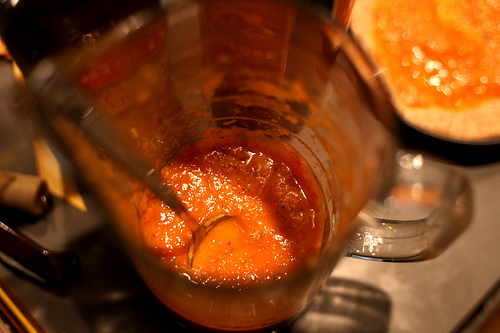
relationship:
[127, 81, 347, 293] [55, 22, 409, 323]
rings around container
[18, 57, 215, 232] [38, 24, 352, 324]
handle leaning against container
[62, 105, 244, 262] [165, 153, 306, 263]
spoon above liquid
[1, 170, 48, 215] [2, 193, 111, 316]
brown handle on top of object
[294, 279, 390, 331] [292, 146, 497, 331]
shadow falling on metal surface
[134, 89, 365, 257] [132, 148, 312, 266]
dish contains food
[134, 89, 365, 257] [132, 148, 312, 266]
dish with food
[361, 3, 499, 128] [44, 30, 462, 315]
food on container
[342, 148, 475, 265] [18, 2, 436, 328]
handle attached to container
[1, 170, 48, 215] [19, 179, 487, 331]
brown handle sitting on counter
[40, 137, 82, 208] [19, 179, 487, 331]
objects sitting on counter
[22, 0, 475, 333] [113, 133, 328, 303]
container containing liquid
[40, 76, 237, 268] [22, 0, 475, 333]
spoon sitting inside container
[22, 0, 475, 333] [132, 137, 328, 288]
container containing food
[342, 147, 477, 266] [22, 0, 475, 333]
handle attached to container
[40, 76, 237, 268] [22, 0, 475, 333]
spoon standing in container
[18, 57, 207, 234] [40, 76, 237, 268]
handle belonging to spoon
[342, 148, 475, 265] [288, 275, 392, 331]
handle casting shadow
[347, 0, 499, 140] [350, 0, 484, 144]
food spread on food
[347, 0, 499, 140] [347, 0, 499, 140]
food spread on food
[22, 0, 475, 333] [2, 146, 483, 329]
container sitting on top of surface